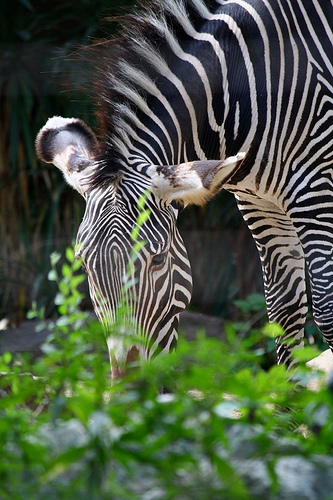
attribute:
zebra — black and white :
[41, 80, 331, 342]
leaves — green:
[149, 402, 190, 457]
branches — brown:
[103, 392, 308, 500]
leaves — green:
[89, 422, 161, 475]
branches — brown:
[139, 387, 235, 424]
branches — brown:
[17, 410, 104, 497]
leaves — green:
[170, 373, 251, 427]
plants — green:
[35, 366, 328, 471]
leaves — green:
[154, 341, 239, 438]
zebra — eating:
[21, 2, 331, 430]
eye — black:
[146, 246, 173, 269]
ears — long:
[35, 100, 243, 214]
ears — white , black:
[32, 111, 251, 214]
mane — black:
[74, 6, 218, 167]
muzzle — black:
[108, 322, 175, 414]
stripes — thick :
[152, 4, 276, 152]